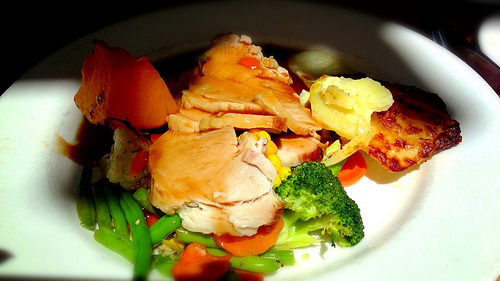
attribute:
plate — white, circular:
[4, 2, 498, 279]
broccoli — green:
[277, 167, 368, 246]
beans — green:
[73, 179, 155, 280]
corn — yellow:
[250, 131, 292, 180]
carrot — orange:
[70, 40, 176, 135]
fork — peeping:
[419, 24, 450, 50]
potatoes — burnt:
[349, 74, 460, 174]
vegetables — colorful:
[49, 43, 176, 280]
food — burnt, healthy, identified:
[77, 38, 437, 277]